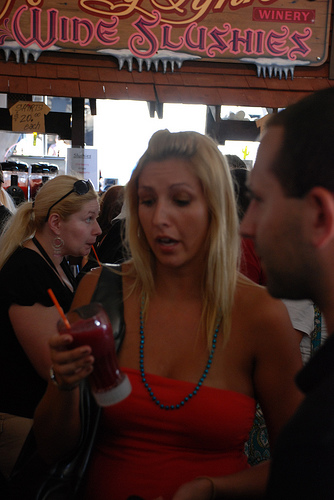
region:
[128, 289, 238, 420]
blue necklace on woman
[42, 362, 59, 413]
silver bracelett on a woman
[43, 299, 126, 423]
red frozen drink with straw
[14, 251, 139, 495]
a large silver purse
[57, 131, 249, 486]
a woman with blonde hair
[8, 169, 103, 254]
a woman with glasses on head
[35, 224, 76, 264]
a silver hoop earring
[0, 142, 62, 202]
2 containers of frozen drinks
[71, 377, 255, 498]
an orange tube top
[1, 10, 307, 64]
wine slushies sign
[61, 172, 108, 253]
Lady with sunglasses on top of head.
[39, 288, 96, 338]
Orange straw in beverage/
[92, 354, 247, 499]
Red tube top.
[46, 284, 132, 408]
Hand holding red beverage with straw.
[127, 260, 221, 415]
Blue beaded necklace.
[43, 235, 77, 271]
Large silver earrings.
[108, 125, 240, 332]
Lady with long blonde hair.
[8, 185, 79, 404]
Black blouse worn by lady.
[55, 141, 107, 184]
Sign posted on pole.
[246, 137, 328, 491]
Man wearing black shirt.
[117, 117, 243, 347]
The woman is blonde.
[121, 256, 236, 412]
Woman wearing a necklace.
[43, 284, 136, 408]
Woman holding a cup.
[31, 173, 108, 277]
Woman is drinking from a straw.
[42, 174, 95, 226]
Sunglasses on woman's head.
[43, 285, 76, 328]
The straw is orange.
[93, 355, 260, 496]
Woman's dress is pink.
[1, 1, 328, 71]
Sign hanging from ceiling.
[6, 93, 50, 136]
Yellow tshirt paper on wall.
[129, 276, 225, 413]
The necklace is blue.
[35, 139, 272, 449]
the woman is looking at her cup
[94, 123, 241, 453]
the woman is wearing a necklace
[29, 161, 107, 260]
the woman is drinking from a straw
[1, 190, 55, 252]
woman's hair is in a ponytail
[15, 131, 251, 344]
the women have blonde hair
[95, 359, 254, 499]
the woman's shirt is red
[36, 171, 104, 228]
the woman has sunglasses on her head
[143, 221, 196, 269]
the woman's mouth is open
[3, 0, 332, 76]
the sign says wine slushies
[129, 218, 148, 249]
the woman is wearing an earring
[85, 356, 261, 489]
The dress is pink.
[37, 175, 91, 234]
Woman wearing sunglasses on her head.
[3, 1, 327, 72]
Sign hanging from the ceiling.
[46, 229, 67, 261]
Woman wearing earrings.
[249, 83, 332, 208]
Man has brown hair.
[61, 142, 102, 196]
The paper is white.